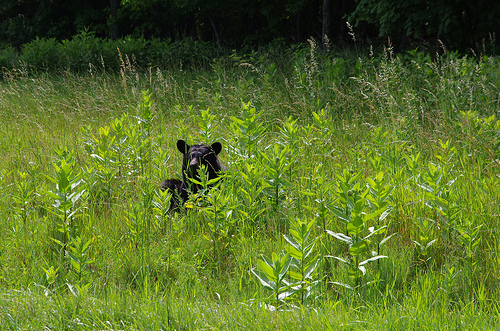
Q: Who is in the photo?
A: Nobody.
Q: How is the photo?
A: Clear.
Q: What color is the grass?
A: Green.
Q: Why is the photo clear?
A: Its during the day.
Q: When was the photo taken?
A: Daytime.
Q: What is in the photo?
A: Animal.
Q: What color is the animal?
A: Black.